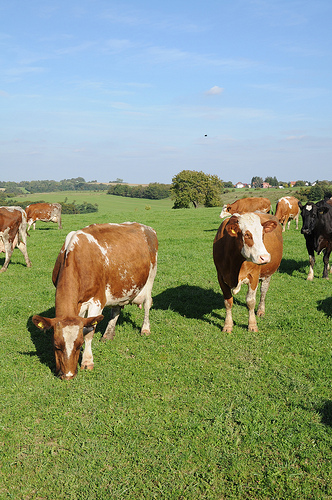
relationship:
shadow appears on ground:
[154, 285, 258, 333] [2, 191, 330, 499]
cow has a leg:
[213, 213, 284, 337] [220, 285, 234, 319]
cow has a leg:
[213, 213, 284, 337] [246, 276, 258, 321]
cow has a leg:
[213, 213, 284, 337] [256, 270, 271, 315]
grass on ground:
[3, 189, 330, 499] [2, 191, 330, 499]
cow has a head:
[213, 213, 284, 337] [225, 213, 277, 264]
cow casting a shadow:
[213, 213, 284, 337] [154, 285, 258, 333]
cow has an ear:
[213, 213, 284, 337] [223, 222, 237, 238]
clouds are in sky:
[22, 44, 328, 164] [9, 0, 332, 184]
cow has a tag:
[30, 219, 162, 384] [36, 321, 44, 332]